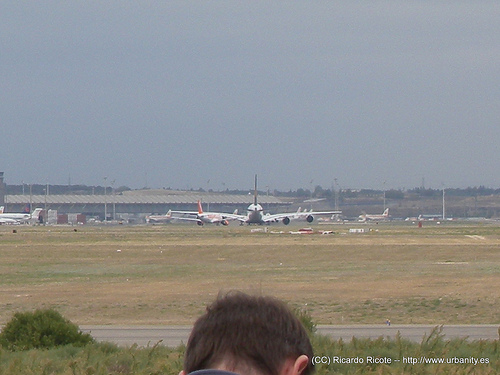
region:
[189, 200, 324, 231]
plane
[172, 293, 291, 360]
brown hair on head of man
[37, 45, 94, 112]
white clouds in blue sky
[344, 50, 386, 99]
white clouds in blue sky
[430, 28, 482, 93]
white clouds in blue sky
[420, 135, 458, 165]
white clouds in blue sky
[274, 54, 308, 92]
white clouds in blue sky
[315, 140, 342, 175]
white clouds in blue sky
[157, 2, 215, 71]
white clouds in blue sky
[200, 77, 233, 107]
white clouds in blue sky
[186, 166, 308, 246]
white plane on runway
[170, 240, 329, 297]
green and brown field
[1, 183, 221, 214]
white roof on far building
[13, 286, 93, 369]
green bush near road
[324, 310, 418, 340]
grey road near field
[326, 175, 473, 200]
trees in far distance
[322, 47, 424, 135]
grey and cloudy sky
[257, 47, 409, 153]
thick clouds cover sky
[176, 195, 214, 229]
red tail on plane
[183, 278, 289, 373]
man has brown hair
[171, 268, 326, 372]
face of the person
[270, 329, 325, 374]
ear of the person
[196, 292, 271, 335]
black hair of person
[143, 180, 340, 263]
a plane in air port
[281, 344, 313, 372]
ear of the person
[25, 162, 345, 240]
a view of air port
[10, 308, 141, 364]
green grass in ground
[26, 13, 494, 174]
a clear view of sky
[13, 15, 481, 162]
a beautiful view of sky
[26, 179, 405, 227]
a group of planes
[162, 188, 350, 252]
plane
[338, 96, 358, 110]
white clouds in blue sky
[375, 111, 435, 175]
white clouds in blue sky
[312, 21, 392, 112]
white clouds in blue sky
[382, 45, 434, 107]
white clouds in blue sky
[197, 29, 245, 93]
white clouds in blue sky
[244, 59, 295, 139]
white clouds in blue sky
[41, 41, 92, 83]
white clouds in blue sky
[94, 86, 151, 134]
white clouds in blue sky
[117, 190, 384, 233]
planes in the distance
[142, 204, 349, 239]
planes in the distance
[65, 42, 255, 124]
the sky is overcast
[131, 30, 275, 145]
the sky is overcast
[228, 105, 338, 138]
the sky is overcast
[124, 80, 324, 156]
the sky is overcast